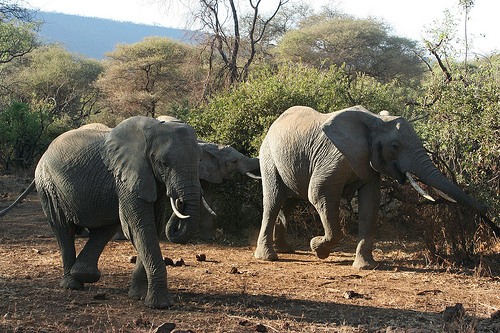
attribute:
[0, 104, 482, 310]
three elephants — walking, moving one direction, in the wild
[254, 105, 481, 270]
elephant — wrinkled, gray, light gray, at right, big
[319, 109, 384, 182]
ear — flapped out, wide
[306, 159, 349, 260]
front right foot — off the ground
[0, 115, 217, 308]
elephant — wrinkled, light gray, gray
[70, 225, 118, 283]
back left foot — crossed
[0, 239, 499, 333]
ground — brown, open, gray, dirt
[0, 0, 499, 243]
trees — in background, leafy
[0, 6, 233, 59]
mountain — in background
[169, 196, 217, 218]
tusks — short, white, white ivory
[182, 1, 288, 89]
tree — bare, bare stemmed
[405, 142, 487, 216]
trunk — sticking out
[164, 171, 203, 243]
trunk — curled, folded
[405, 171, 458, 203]
tusks — white, white ivory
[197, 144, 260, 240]
elephant — partially hidden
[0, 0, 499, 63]
sky — blue, clear